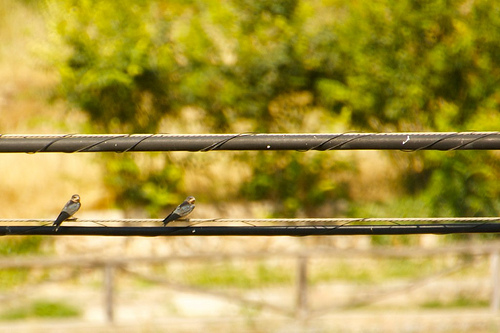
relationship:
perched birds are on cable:
[45, 187, 210, 249] [7, 113, 497, 260]